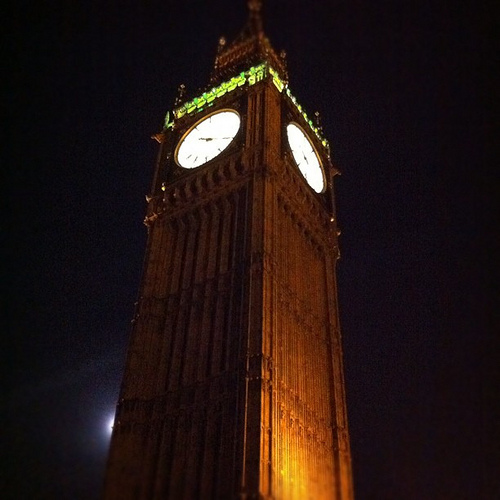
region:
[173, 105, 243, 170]
a clock on the tower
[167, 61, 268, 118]
a row of green lights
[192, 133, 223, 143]
the hands of a clock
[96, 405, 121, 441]
the edge of the moon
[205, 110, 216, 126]
a tick on the clock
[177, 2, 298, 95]
the tip of the tower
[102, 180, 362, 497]
a yellow tower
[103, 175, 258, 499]
the face of a tower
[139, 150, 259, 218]
ornamentation on the tower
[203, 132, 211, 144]
the center of the clock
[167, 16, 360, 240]
Two clocks on the tower.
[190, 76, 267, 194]
White clock with black hands.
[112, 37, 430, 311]
Tower with two clocks.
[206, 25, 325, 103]
Steeple on the tower.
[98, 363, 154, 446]
Moon behind the tower.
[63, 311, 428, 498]
Night sky behind tower.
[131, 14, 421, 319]
Tower in the night sky.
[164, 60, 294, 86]
Lights on the tower.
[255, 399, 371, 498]
Bright part of the tower.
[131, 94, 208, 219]
Corner of the building.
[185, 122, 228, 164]
a clock face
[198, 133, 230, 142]
hands of a clock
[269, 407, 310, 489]
light shining on a building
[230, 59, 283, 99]
lights of a building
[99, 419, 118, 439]
a light behind a building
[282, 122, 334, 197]
a clock face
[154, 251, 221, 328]
the wall of a building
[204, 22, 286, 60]
the top of a tall building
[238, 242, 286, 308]
the corner of a building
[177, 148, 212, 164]
the numbers on a clock face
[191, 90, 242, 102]
bright green light at the top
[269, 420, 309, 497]
light shining onto the building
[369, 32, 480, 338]
the black night sky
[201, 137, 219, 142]
black hands on the clock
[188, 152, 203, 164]
black roman numerals on the clock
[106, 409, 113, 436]
a light shining next to the building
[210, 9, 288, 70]
a bell tower on top of the building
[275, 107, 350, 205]
a lit clock at the top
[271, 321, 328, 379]
an etched pattern in the stone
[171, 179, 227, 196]
carvings beneath the clock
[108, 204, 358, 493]
this is a clock tower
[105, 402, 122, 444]
this is the moon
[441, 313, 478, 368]
this is the color black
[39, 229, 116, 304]
this is the sky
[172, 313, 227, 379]
this is the color brown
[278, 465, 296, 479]
this is the color gold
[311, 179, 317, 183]
this is the color white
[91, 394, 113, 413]
this is the color blue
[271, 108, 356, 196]
this is a clock face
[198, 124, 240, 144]
these are clock hands